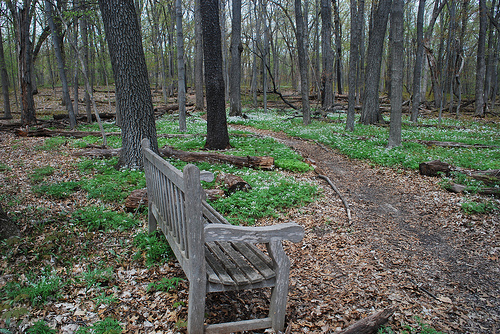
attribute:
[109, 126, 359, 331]
bench — brown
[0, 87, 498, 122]
fence — covered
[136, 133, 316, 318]
bench — empty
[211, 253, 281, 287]
slat — wooden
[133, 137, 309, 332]
bench — light brown, brown, wooden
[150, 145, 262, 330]
bench — brown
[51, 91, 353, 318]
bench — brown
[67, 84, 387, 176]
fence — covered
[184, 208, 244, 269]
slat — wooden